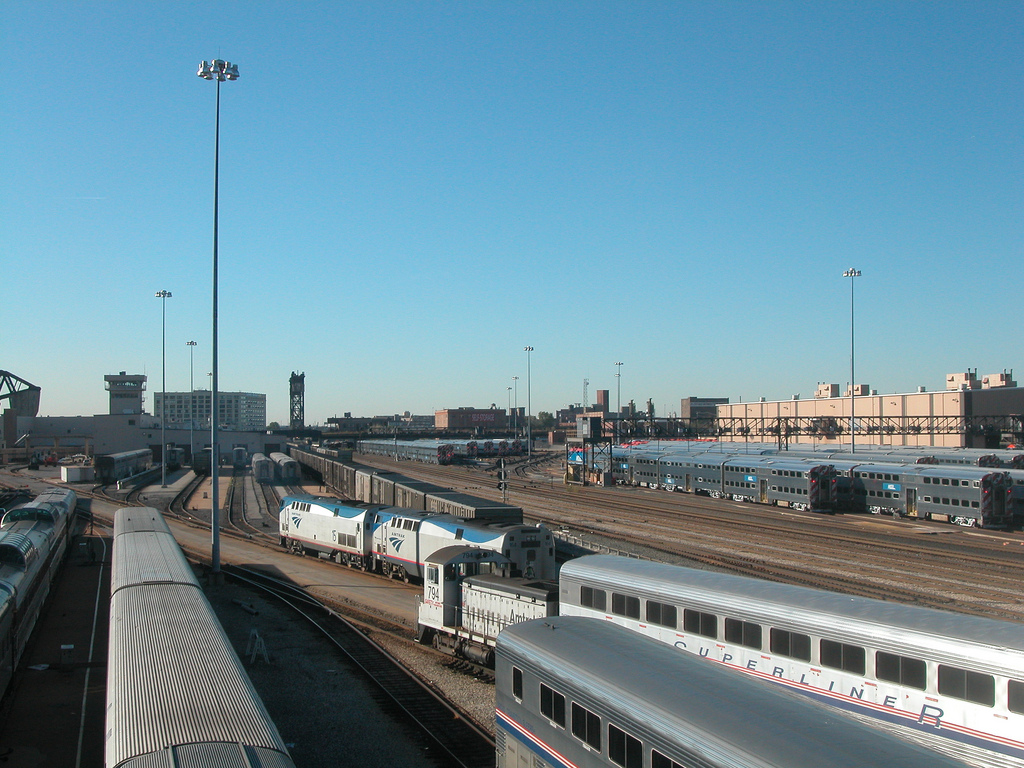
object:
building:
[677, 366, 1023, 450]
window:
[820, 637, 867, 679]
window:
[172, 402, 216, 429]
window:
[216, 396, 252, 429]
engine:
[402, 539, 567, 687]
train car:
[100, 579, 300, 766]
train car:
[110, 528, 208, 595]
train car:
[112, 504, 177, 538]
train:
[99, 503, 300, 767]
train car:
[627, 451, 668, 489]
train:
[818, 458, 1020, 527]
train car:
[846, 464, 1015, 532]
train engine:
[275, 491, 397, 574]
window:
[510, 663, 524, 702]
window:
[534, 679, 570, 732]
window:
[569, 698, 603, 756]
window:
[644, 744, 680, 764]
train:
[488, 612, 978, 766]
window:
[605, 718, 644, 764]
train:
[411, 541, 1023, 766]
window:
[580, 582, 604, 609]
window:
[682, 607, 719, 641]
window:
[723, 617, 763, 653]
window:
[611, 591, 642, 623]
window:
[644, 600, 679, 633]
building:
[151, 388, 266, 432]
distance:
[0, 0, 1022, 450]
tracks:
[257, 482, 280, 525]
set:
[122, 464, 183, 508]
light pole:
[209, 43, 223, 574]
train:
[0, 484, 83, 695]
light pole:
[160, 285, 169, 490]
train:
[91, 447, 156, 486]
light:
[147, 279, 183, 312]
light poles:
[525, 343, 534, 463]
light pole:
[849, 265, 858, 456]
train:
[564, 444, 845, 515]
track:
[180, 547, 496, 768]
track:
[177, 545, 497, 676]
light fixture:
[192, 52, 250, 92]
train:
[278, 491, 558, 591]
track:
[168, 473, 216, 529]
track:
[72, 518, 113, 766]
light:
[184, 340, 199, 347]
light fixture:
[833, 258, 872, 284]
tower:
[284, 365, 311, 447]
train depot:
[6, 428, 1011, 764]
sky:
[0, 0, 1024, 435]